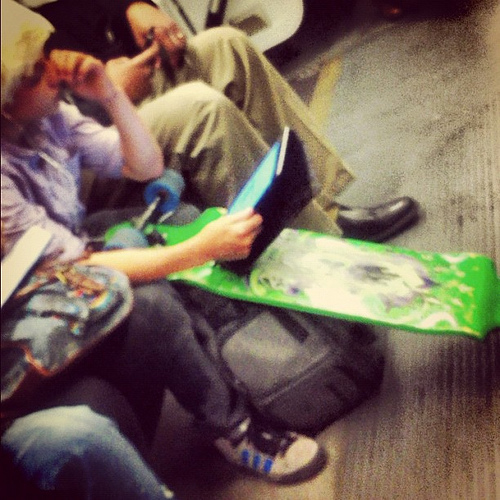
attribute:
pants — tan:
[152, 0, 360, 221]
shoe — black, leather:
[325, 189, 424, 249]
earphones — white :
[4, 88, 26, 124]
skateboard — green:
[143, 204, 494, 338]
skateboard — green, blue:
[95, 169, 498, 349]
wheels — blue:
[99, 167, 195, 259]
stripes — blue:
[235, 444, 276, 482]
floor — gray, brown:
[361, 31, 490, 180]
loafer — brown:
[333, 185, 423, 239]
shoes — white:
[193, 413, 333, 491]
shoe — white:
[206, 414, 329, 492]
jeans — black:
[117, 282, 251, 442]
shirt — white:
[2, 98, 131, 258]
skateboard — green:
[140, 178, 485, 359]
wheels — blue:
[125, 163, 214, 244]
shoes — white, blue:
[213, 410, 346, 494]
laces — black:
[235, 403, 304, 459]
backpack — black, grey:
[211, 273, 377, 410]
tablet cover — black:
[235, 142, 345, 278]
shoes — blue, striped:
[214, 419, 344, 493]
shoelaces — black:
[246, 406, 316, 457]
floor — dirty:
[322, 49, 444, 167]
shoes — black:
[345, 190, 470, 272]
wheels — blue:
[138, 171, 198, 217]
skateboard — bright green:
[196, 201, 483, 353]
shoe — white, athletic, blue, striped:
[197, 406, 333, 486]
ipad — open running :
[212, 122, 298, 265]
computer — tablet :
[203, 111, 294, 258]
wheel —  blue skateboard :
[142, 170, 190, 206]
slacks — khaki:
[19, 5, 455, 239]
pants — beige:
[97, 24, 347, 240]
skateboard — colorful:
[2, 234, 136, 415]